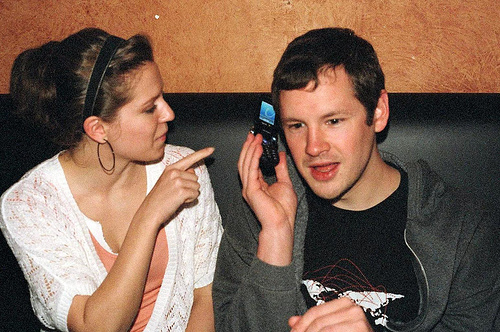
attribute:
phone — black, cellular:
[245, 95, 291, 175]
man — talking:
[206, 16, 491, 330]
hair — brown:
[6, 20, 136, 140]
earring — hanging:
[94, 136, 115, 170]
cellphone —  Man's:
[253, 102, 282, 171]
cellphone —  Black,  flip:
[252, 97, 281, 173]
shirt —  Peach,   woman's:
[90, 233, 166, 329]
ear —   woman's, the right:
[82, 115, 107, 144]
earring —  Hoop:
[93, 139, 114, 175]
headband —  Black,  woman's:
[84, 33, 120, 131]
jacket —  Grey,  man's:
[213, 150, 498, 328]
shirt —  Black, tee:
[301, 159, 421, 329]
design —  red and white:
[299, 257, 409, 329]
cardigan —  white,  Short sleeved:
[2, 146, 223, 329]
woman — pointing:
[2, 26, 222, 327]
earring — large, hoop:
[88, 130, 121, 182]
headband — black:
[71, 26, 125, 131]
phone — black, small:
[240, 93, 280, 179]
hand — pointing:
[133, 139, 216, 229]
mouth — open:
[304, 157, 340, 184]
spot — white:
[152, 10, 166, 22]